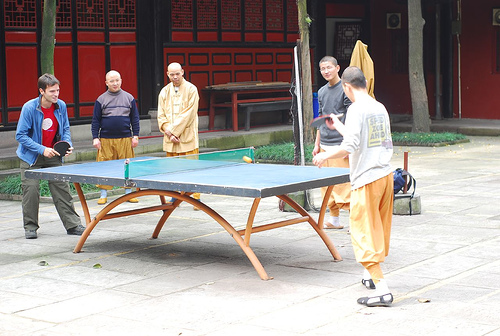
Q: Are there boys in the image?
A: No, there are no boys.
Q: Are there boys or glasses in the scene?
A: No, there are no boys or glasses.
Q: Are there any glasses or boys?
A: No, there are no boys or glasses.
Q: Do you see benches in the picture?
A: Yes, there is a bench.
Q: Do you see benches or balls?
A: Yes, there is a bench.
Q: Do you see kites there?
A: No, there are no kites.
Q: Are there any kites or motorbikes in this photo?
A: No, there are no kites or motorbikes.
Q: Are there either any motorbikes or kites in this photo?
A: No, there are no kites or motorbikes.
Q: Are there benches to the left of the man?
A: Yes, there is a bench to the left of the man.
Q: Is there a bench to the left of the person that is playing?
A: Yes, there is a bench to the left of the man.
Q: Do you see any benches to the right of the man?
A: No, the bench is to the left of the man.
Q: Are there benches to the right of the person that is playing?
A: No, the bench is to the left of the man.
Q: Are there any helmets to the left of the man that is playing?
A: No, there is a bench to the left of the man.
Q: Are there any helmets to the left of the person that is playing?
A: No, there is a bench to the left of the man.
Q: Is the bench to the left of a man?
A: Yes, the bench is to the left of a man.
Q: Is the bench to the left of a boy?
A: No, the bench is to the left of a man.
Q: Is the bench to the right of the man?
A: No, the bench is to the left of the man.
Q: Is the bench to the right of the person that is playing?
A: No, the bench is to the left of the man.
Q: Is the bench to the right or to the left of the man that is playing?
A: The bench is to the left of the man.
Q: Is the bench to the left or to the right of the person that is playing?
A: The bench is to the left of the man.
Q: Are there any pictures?
A: No, there are no pictures.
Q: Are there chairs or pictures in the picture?
A: No, there are no pictures or chairs.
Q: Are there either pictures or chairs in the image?
A: No, there are no pictures or chairs.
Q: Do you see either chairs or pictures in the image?
A: No, there are no pictures or chairs.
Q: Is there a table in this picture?
A: Yes, there is a table.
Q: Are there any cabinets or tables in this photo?
A: Yes, there is a table.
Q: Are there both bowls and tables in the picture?
A: No, there is a table but no bowls.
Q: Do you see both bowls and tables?
A: No, there is a table but no bowls.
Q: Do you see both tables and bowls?
A: No, there is a table but no bowls.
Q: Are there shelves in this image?
A: No, there are no shelves.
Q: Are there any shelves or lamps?
A: No, there are no shelves or lamps.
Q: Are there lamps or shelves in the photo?
A: No, there are no shelves or lamps.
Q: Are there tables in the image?
A: Yes, there is a table.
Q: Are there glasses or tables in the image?
A: Yes, there is a table.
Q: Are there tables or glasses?
A: Yes, there is a table.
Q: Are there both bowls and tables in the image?
A: No, there is a table but no bowls.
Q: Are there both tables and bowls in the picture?
A: No, there is a table but no bowls.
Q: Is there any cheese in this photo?
A: No, there is no cheese.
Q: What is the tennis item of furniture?
A: The piece of furniture is a table.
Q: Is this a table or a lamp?
A: This is a table.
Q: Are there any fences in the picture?
A: No, there are no fences.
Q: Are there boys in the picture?
A: No, there are no boys.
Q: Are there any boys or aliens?
A: No, there are no boys or aliens.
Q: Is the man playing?
A: Yes, the man is playing.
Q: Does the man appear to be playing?
A: Yes, the man is playing.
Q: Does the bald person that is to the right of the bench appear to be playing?
A: Yes, the man is playing.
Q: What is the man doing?
A: The man is playing.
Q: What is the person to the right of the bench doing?
A: The man is playing.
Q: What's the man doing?
A: The man is playing.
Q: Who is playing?
A: The man is playing.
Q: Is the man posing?
A: No, the man is playing.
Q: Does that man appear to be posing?
A: No, the man is playing.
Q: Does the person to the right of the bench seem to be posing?
A: No, the man is playing.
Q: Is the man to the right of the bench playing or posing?
A: The man is playing.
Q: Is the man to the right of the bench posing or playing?
A: The man is playing.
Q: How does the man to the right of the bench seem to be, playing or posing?
A: The man is playing.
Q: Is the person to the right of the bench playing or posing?
A: The man is playing.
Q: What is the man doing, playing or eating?
A: The man is playing.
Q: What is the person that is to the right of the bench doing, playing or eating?
A: The man is playing.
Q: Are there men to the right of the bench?
A: Yes, there is a man to the right of the bench.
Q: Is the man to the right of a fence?
A: No, the man is to the right of the bench.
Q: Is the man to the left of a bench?
A: No, the man is to the right of a bench.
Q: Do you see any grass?
A: Yes, there is grass.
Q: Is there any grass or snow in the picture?
A: Yes, there is grass.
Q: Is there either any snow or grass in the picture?
A: Yes, there is grass.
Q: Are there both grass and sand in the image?
A: No, there is grass but no sand.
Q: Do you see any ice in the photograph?
A: No, there is no ice.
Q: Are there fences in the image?
A: No, there are no fences.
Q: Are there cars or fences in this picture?
A: No, there are no fences or cars.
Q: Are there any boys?
A: No, there are no boys.